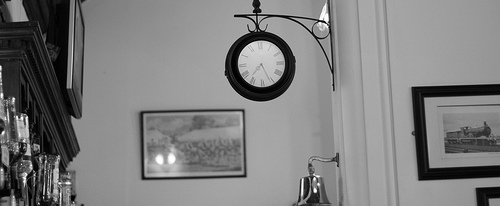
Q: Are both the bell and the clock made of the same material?
A: Yes, both the bell and the clock are made of metal.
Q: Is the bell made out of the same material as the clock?
A: Yes, both the bell and the clock are made of metal.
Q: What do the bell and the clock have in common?
A: The material, both the bell and the clock are metallic.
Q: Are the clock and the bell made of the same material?
A: Yes, both the clock and the bell are made of metal.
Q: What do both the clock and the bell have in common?
A: The material, both the clock and the bell are metallic.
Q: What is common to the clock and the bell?
A: The material, both the clock and the bell are metallic.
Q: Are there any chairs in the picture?
A: No, there are no chairs.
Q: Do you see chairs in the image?
A: No, there are no chairs.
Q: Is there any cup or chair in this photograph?
A: No, there are no chairs or cups.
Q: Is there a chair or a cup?
A: No, there are no chairs or cups.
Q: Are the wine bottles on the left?
A: Yes, the wine bottles are on the left of the image.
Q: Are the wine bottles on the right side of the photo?
A: No, the wine bottles are on the left of the image.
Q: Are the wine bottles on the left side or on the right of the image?
A: The wine bottles are on the left of the image.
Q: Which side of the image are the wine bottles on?
A: The wine bottles are on the left of the image.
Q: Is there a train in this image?
A: Yes, there is a train.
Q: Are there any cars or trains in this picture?
A: Yes, there is a train.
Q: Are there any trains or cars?
A: Yes, there is a train.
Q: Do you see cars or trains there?
A: Yes, there is a train.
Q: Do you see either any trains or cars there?
A: Yes, there is a train.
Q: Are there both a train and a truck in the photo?
A: No, there is a train but no trucks.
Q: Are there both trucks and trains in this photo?
A: No, there is a train but no trucks.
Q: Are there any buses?
A: No, there are no buses.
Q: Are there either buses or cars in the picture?
A: No, there are no buses or cars.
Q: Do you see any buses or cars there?
A: No, there are no buses or cars.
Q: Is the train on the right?
A: Yes, the train is on the right of the image.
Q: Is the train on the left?
A: No, the train is on the right of the image.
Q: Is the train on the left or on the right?
A: The train is on the right of the image.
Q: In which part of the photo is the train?
A: The train is on the right of the image.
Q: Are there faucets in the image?
A: No, there are no faucets.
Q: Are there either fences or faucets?
A: No, there are no faucets or fences.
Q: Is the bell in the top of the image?
A: No, the bell is in the bottom of the image.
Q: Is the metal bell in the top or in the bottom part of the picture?
A: The bell is in the bottom of the image.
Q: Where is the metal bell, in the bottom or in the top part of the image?
A: The bell is in the bottom of the image.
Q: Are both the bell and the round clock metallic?
A: Yes, both the bell and the clock are metallic.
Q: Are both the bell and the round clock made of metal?
A: Yes, both the bell and the clock are made of metal.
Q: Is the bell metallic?
A: Yes, the bell is metallic.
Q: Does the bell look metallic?
A: Yes, the bell is metallic.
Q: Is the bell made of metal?
A: Yes, the bell is made of metal.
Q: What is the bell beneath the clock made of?
A: The bell is made of metal.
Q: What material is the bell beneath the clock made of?
A: The bell is made of metal.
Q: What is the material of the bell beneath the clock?
A: The bell is made of metal.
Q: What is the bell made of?
A: The bell is made of metal.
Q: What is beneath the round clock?
A: The bell is beneath the clock.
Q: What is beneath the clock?
A: The bell is beneath the clock.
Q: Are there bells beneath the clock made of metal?
A: Yes, there is a bell beneath the clock.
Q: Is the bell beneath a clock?
A: Yes, the bell is beneath a clock.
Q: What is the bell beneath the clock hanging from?
A: The bell is hanging from the wall.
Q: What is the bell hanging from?
A: The bell is hanging from the wall.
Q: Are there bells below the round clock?
A: Yes, there is a bell below the clock.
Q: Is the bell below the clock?
A: Yes, the bell is below the clock.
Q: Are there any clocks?
A: Yes, there is a clock.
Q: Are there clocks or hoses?
A: Yes, there is a clock.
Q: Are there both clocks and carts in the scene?
A: No, there is a clock but no carts.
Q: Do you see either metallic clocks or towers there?
A: Yes, there is a metal clock.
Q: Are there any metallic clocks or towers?
A: Yes, there is a metal clock.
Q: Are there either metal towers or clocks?
A: Yes, there is a metal clock.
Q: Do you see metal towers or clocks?
A: Yes, there is a metal clock.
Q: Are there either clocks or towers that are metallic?
A: Yes, the clock is metallic.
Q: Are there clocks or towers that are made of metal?
A: Yes, the clock is made of metal.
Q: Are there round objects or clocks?
A: Yes, there is a round clock.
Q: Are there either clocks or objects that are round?
A: Yes, the clock is round.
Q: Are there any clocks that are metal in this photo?
A: Yes, there is a metal clock.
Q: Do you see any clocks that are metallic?
A: Yes, there is a clock that is metallic.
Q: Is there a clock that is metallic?
A: Yes, there is a clock that is metallic.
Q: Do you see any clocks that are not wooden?
A: Yes, there is a metallic clock.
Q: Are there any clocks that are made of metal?
A: Yes, there is a clock that is made of metal.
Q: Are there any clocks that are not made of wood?
A: Yes, there is a clock that is made of metal.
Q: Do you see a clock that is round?
A: Yes, there is a round clock.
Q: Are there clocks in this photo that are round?
A: Yes, there is a clock that is round.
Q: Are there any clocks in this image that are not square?
A: Yes, there is a round clock.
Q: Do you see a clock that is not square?
A: Yes, there is a round clock.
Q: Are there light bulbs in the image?
A: No, there are no light bulbs.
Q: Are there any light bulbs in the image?
A: No, there are no light bulbs.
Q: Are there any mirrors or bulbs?
A: No, there are no bulbs or mirrors.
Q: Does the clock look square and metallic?
A: No, the clock is metallic but round.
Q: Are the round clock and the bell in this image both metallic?
A: Yes, both the clock and the bell are metallic.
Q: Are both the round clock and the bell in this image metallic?
A: Yes, both the clock and the bell are metallic.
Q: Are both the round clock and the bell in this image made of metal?
A: Yes, both the clock and the bell are made of metal.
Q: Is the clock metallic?
A: Yes, the clock is metallic.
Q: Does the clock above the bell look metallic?
A: Yes, the clock is metallic.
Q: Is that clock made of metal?
A: Yes, the clock is made of metal.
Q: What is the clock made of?
A: The clock is made of metal.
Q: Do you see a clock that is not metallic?
A: No, there is a clock but it is metallic.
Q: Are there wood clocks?
A: No, there is a clock but it is made of metal.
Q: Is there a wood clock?
A: No, there is a clock but it is made of metal.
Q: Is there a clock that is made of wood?
A: No, there is a clock but it is made of metal.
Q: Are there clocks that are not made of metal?
A: No, there is a clock but it is made of metal.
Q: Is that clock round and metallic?
A: Yes, the clock is round and metallic.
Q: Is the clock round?
A: Yes, the clock is round.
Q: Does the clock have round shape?
A: Yes, the clock is round.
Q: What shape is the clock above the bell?
A: The clock is round.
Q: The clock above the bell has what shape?
A: The clock is round.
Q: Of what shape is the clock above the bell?
A: The clock is round.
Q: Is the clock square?
A: No, the clock is round.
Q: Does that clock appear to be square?
A: No, the clock is round.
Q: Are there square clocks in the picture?
A: No, there is a clock but it is round.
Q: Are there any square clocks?
A: No, there is a clock but it is round.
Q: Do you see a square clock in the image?
A: No, there is a clock but it is round.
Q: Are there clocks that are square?
A: No, there is a clock but it is round.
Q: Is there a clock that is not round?
A: No, there is a clock but it is round.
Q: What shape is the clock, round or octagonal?
A: The clock is round.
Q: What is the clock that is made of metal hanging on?
A: The clock is hanging on the wall.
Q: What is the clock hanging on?
A: The clock is hanging on the wall.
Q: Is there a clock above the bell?
A: Yes, there is a clock above the bell.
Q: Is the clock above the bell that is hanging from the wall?
A: Yes, the clock is above the bell.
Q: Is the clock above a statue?
A: No, the clock is above the bell.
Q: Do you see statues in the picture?
A: No, there are no statues.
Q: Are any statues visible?
A: No, there are no statues.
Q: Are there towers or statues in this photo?
A: No, there are no statues or towers.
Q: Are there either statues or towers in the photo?
A: No, there are no statues or towers.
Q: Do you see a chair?
A: No, there are no chairs.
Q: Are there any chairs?
A: No, there are no chairs.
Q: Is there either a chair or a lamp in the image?
A: No, there are no chairs or lamps.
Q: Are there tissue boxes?
A: No, there are no tissue boxes.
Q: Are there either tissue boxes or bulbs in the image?
A: No, there are no tissue boxes or bulbs.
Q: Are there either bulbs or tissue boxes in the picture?
A: No, there are no tissue boxes or bulbs.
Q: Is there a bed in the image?
A: No, there are no beds.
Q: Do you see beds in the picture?
A: No, there are no beds.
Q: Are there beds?
A: No, there are no beds.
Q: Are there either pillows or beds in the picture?
A: No, there are no beds or pillows.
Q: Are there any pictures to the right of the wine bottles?
A: Yes, there is a picture to the right of the wine bottles.